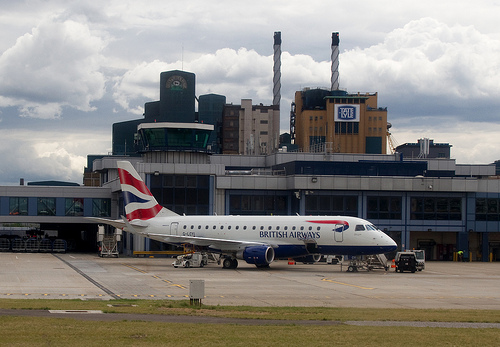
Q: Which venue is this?
A: This is an airport.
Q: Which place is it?
A: It is an airport.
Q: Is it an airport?
A: Yes, it is an airport.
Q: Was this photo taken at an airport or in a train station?
A: It was taken at an airport.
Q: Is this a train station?
A: No, it is an airport.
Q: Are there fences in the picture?
A: No, there are no fences.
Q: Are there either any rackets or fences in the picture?
A: No, there are no fences or rackets.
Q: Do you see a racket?
A: No, there are no rackets.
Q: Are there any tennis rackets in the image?
A: No, there are no tennis rackets.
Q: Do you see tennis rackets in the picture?
A: No, there are no tennis rackets.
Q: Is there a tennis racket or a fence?
A: No, there are no rackets or fences.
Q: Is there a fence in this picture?
A: No, there are no fences.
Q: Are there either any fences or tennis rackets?
A: No, there are no fences or tennis rackets.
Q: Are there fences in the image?
A: No, there are no fences.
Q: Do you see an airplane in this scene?
A: Yes, there is an airplane.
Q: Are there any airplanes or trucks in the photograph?
A: Yes, there is an airplane.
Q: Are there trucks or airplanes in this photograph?
A: Yes, there is an airplane.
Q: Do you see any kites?
A: No, there are no kites.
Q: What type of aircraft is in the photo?
A: The aircraft is an airplane.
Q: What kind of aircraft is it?
A: The aircraft is an airplane.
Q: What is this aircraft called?
A: This is an airplane.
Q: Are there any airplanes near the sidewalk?
A: Yes, there is an airplane near the sidewalk.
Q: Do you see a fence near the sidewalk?
A: No, there is an airplane near the sidewalk.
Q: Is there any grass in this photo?
A: Yes, there is grass.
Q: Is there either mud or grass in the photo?
A: Yes, there is grass.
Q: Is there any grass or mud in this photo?
A: Yes, there is grass.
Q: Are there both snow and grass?
A: No, there is grass but no snow.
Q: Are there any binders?
A: No, there are no binders.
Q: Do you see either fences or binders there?
A: No, there are no binders or fences.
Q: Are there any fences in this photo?
A: No, there are no fences.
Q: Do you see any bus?
A: No, there are no buses.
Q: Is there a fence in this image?
A: No, there are no fences.